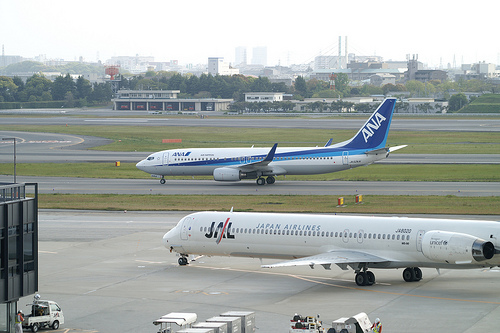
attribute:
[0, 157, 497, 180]
grass — green 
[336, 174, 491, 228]
grass — patch 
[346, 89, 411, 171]
tail — blue 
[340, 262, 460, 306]
wheels — Rear 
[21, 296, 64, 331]
truck — small white, lower left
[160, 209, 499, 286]
plane — white , white passenger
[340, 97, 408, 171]
blue tail — blue 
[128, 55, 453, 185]
plane — side , blue stripe, two shades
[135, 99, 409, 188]
plane — white , blue , JAL passenger 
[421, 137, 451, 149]
greenfield — green 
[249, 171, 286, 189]
wheel — front landing 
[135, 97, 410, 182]
airplane — Large ANA passenger 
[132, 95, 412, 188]
airplane — blue , white  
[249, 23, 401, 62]
sky — white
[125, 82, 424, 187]
airplane — Passenger blue , take-off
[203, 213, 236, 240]
logo — company 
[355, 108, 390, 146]
letters — white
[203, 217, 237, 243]
writing — Japan Airlines 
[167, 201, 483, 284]
airplane — passenger 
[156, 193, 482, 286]
plane — white 